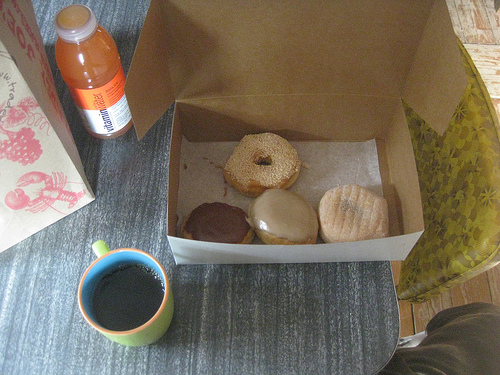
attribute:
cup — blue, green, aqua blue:
[75, 239, 176, 349]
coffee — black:
[93, 262, 162, 333]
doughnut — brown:
[182, 201, 255, 245]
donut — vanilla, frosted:
[245, 189, 319, 248]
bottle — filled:
[54, 6, 133, 141]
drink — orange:
[51, 3, 138, 142]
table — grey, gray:
[1, 1, 400, 374]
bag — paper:
[1, 1, 95, 255]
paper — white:
[177, 132, 227, 204]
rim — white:
[107, 245, 165, 269]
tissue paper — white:
[300, 139, 393, 185]